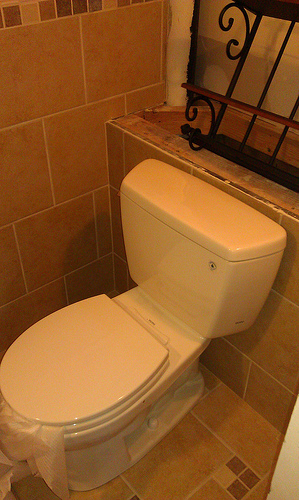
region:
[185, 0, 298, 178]
wood and metal rack on a wall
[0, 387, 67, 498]
toilet paper caught in toilet seat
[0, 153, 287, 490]
white plastic and porcelain toilet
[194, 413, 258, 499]
brown white and light brown tiles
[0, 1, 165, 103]
brown white and light brown tiles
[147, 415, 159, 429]
bolt covering on toilet base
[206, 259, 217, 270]
toilet company logo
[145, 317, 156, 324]
toilet company logo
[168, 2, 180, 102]
broken drywall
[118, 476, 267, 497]
section of tile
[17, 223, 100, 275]
ceramic tile on wall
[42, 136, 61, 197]
grout lines for tiles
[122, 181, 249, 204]
part of toilet lid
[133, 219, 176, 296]
back portion of toilet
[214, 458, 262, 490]
ceramic tile on floor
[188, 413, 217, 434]
grout lines on floor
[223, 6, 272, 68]
black rail behind toilet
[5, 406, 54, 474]
protective toilet seat cover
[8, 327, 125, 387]
part of toilet lid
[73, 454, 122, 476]
bottom part of toilet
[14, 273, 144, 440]
the toilet is white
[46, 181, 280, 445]
the toilet is white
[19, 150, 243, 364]
the toilet is white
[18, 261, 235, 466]
the toilet is white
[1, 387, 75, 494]
white paper stuck under toilet seat lid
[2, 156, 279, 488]
white toilet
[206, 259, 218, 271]
black logo on a white toilet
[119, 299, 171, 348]
white hinge between toilet and lid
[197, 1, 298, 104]
exposed sheet rock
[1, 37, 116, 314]
brown tile wall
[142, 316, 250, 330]
brand name written on toilet twice in black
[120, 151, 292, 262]
lid to the toilet's water tank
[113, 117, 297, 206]
exposed wall board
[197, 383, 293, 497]
brown tile pattern on the floor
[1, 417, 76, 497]
toilet paper hanging out of a toilet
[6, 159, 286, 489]
a white toilet with a missing flush handle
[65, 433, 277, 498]
a brown tile floor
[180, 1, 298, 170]
a black rail shelf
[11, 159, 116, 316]
a brown tile wall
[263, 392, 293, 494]
the corner of a white counter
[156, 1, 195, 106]
a white pipe visible in a wall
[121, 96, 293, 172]
a shelf behind a toilet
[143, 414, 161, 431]
a white cap covering a bolt attaching a toilet to the floor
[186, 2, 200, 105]
black paint on a white pipe